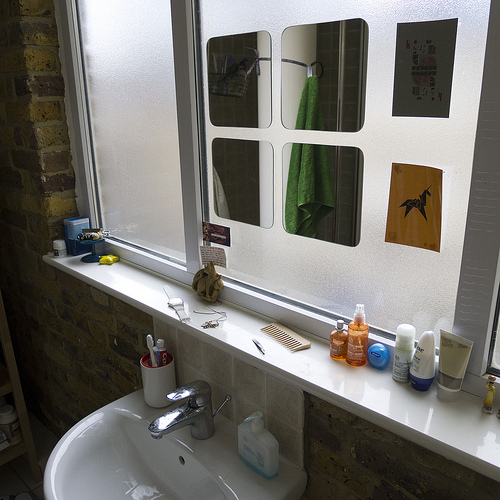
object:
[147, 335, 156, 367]
toothbrush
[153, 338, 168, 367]
toothpaste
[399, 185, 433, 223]
unicorn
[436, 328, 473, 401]
toiletry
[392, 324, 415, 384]
toiletry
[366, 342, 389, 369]
toiletry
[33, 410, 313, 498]
sink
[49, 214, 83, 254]
containers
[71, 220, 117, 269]
knickknackkers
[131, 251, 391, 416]
white counter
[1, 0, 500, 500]
wall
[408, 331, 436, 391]
bottle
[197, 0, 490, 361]
window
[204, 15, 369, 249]
mirrors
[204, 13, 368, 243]
squares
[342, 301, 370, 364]
spray bottle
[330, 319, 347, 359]
spray bottle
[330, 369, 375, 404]
counter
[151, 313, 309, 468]
backsplash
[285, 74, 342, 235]
towel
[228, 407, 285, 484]
container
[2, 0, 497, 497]
bathroom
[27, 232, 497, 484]
shelf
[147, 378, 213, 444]
faucet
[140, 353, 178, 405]
cup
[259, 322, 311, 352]
comb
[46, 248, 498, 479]
counter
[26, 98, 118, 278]
corner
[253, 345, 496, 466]
counter